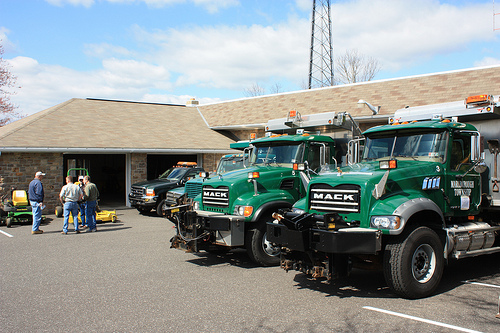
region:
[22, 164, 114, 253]
the people are talking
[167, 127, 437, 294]
the trucks are green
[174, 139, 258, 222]
the trucks are green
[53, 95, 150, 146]
the roof is beige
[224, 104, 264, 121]
the roof is beige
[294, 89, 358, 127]
the roof is beige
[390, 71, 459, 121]
the roof is beige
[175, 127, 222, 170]
the roof is beige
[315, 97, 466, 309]
the truck is parked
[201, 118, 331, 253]
the truck is parked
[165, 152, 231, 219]
the truck is parked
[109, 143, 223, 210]
the truck is parked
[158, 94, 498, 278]
Two large green trucks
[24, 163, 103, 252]
Four men in a group talking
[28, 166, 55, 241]
A man in a white baseball cap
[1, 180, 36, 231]
John Deere lawn equipment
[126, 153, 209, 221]
The front of a black pick up truck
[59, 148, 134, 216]
A garage door opening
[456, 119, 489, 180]
A large side view mirror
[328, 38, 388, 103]
Winter bare tree top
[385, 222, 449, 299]
Large black tire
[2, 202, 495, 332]
A parking lot with lines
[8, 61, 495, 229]
large work building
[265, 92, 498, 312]
big green mack truck on the right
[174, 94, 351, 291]
big green mack truck on the left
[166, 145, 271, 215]
green pick up next to mack truck on the left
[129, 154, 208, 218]
black pick up with orange light bar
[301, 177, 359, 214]
mack emblem on the right truck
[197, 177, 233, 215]
mack emblem on the left truck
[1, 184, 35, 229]
green and yellow lawn mower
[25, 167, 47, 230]
man standing in front of lawn mower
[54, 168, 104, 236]
group of three men standing together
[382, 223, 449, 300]
black wheel of a truck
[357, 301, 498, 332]
white line on a ground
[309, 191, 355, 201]
text on the front of truck reading MACK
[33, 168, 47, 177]
hat on a a man's head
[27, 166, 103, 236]
four men standing around and talking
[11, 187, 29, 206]
a yellow seat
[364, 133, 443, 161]
winshield of a truck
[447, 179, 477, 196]
white print on a truck's door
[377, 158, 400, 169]
orange and white truck lights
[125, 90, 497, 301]
parked trucks on a lot